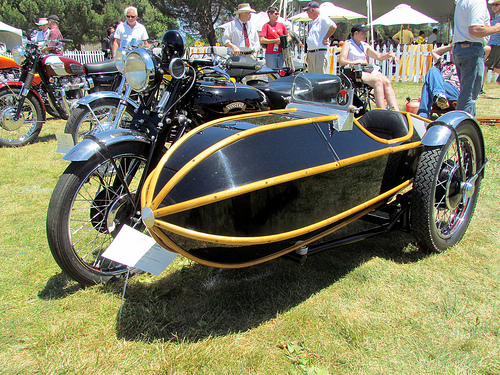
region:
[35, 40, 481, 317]
Zeppelin shaped motorcycle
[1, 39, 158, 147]
Red motorcycle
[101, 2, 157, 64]
Gray haired man with glasses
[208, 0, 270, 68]
Man with red tie and cowboy hat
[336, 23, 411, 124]
Sitting woman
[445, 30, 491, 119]
A pair of jeans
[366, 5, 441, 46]
An umbrella over a table for shade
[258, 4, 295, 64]
A man in a red shirt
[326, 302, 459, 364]
A section of grass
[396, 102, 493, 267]
The back tire of a vehicle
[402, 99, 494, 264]
wheel on a motorcycle sidecar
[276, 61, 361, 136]
windshield on a motorcycle sidecar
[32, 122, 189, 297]
front wheel on a motorcycle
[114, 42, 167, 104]
front headlight on a motorcycle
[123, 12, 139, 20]
glasses on a persons face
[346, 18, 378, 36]
hat on a persons head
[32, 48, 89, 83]
red and white gas tank on a motorcycle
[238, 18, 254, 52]
tie on a persons neck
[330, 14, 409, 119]
person with shorts sitting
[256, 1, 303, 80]
person with a red shirt standing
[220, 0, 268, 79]
man wearing hat with wide brim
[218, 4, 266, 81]
man wearing white collared shirt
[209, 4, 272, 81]
man wearing red neck tie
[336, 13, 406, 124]
woman wearing black hat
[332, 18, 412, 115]
woman wearing white shirt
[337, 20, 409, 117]
woman sitting in chair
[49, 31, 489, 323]
motorcycle with sidecar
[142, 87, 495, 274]
black and yellow sidecar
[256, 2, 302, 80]
man in red shirt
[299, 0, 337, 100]
man wearing khaki pants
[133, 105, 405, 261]
Yellow lines on the vehicle.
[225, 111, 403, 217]
The vehicle is black.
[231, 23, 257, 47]
Man is wearing a tie.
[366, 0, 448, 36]
The umbrella is white.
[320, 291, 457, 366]
The grass is green.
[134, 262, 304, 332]
The vehicle is casting a shadow.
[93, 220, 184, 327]
Sign in front of the vehicle.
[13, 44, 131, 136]
Motorcycle in the background.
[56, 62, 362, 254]
Motorcycle next to the vehicle.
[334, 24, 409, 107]
Woman sitting in a chair.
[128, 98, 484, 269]
sidecar on a motorcycle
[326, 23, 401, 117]
person sitting in a wheelchair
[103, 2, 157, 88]
this man has a receding hairline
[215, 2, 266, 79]
man wearing a red tie and a hat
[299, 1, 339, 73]
man wearing khakis and a ball cap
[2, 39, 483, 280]
several motorcycles parked together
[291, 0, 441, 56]
tables shaded by umbrellas nearby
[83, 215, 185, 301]
placard in front of a motorcycle on display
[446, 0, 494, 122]
man wearing blue jeans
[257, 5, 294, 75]
person wearing a red t-shirt